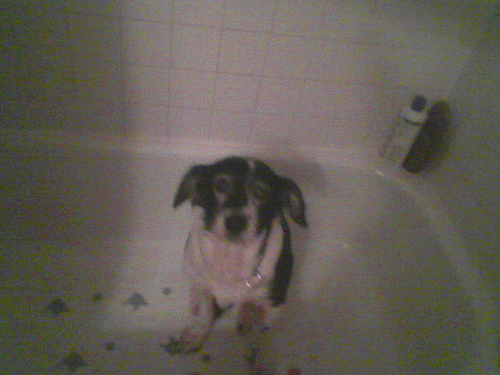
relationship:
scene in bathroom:
[63, 43, 447, 332] [48, 60, 370, 312]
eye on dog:
[207, 180, 235, 196] [170, 154, 307, 363]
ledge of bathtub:
[13, 135, 365, 162] [9, 127, 484, 357]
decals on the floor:
[42, 295, 71, 316] [16, 219, 361, 359]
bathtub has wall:
[12, 132, 499, 373] [8, 6, 497, 155]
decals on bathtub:
[42, 295, 71, 316] [12, 132, 499, 373]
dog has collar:
[170, 154, 307, 363] [195, 221, 280, 250]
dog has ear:
[170, 154, 307, 363] [275, 174, 315, 235]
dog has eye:
[170, 154, 307, 363] [242, 183, 265, 201]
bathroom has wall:
[6, 128, 498, 373] [6, 4, 498, 140]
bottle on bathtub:
[379, 95, 427, 164] [12, 132, 499, 373]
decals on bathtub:
[42, 284, 156, 369] [0, 140, 499, 374]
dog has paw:
[170, 154, 307, 363] [162, 323, 207, 355]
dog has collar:
[161, 154, 315, 363] [252, 234, 275, 274]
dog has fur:
[170, 154, 307, 363] [193, 248, 247, 295]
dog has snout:
[170, 154, 307, 363] [221, 208, 251, 228]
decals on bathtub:
[42, 295, 71, 316] [0, 140, 499, 374]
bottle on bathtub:
[379, 95, 427, 164] [0, 140, 499, 374]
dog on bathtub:
[170, 154, 307, 363] [0, 140, 499, 374]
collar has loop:
[241, 226, 284, 295] [242, 264, 265, 293]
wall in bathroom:
[8, 6, 497, 155] [6, 4, 498, 371]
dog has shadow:
[170, 154, 307, 363] [279, 141, 337, 188]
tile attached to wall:
[170, 21, 221, 72] [10, 1, 455, 174]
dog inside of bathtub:
[170, 154, 307, 363] [0, 140, 499, 374]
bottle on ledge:
[372, 90, 428, 178] [350, 149, 483, 331]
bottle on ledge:
[393, 100, 453, 178] [390, 160, 483, 340]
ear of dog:
[277, 169, 313, 232] [170, 154, 307, 363]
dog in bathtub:
[170, 154, 307, 363] [0, 140, 499, 374]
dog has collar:
[170, 154, 307, 363] [219, 227, 271, 288]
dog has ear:
[170, 154, 307, 363] [275, 172, 311, 233]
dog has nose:
[170, 154, 307, 363] [220, 211, 250, 236]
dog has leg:
[170, 154, 307, 363] [159, 283, 214, 361]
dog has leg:
[170, 154, 307, 363] [237, 296, 288, 373]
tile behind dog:
[5, 2, 272, 142] [170, 154, 307, 363]